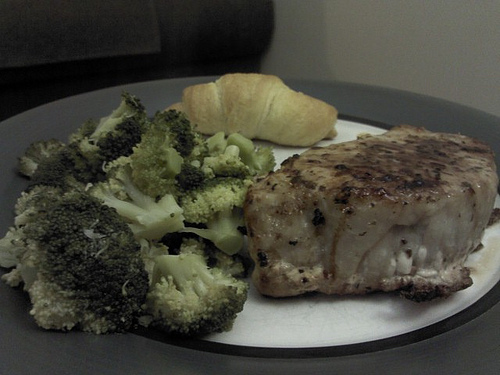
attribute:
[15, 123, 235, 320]
broccoli — green, cooked, light green, vegetable, florets, abundant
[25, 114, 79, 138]
plate — white, gray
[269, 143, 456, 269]
meat — seasoned, cooked, sliced, pork, seared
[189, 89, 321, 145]
croissant — brown, rolled up, toasted, small, flaky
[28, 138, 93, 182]
broccoli — pieced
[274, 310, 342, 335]
center — white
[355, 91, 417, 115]
rim — gray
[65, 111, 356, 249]
food types — 3, meat, broccoli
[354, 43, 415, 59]
wall — white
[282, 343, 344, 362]
band — black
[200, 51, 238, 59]
table — gray